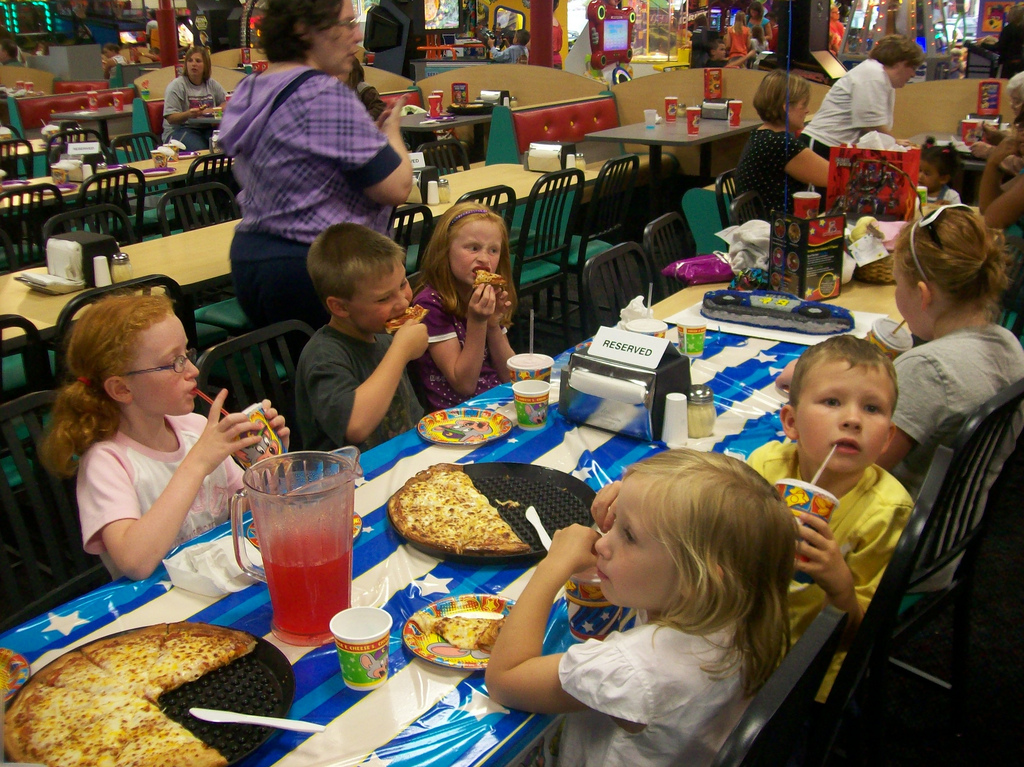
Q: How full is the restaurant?
A: Mostly empty.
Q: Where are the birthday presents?
A: At the end of the table.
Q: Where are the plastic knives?
A: By each pizza.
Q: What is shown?
A: Kids at a birthday party in a pizza restaurant.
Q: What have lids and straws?
A: The drinking cups.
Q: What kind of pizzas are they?
A: Cheese.